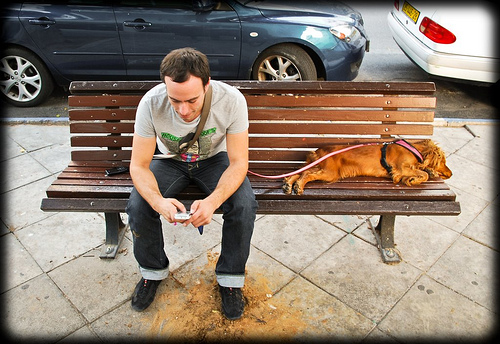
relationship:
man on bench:
[123, 48, 257, 323] [37, 79, 462, 219]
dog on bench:
[275, 137, 457, 197] [37, 79, 462, 219]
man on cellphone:
[123, 48, 257, 323] [171, 210, 193, 221]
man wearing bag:
[123, 48, 257, 323] [139, 81, 215, 160]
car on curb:
[0, 0, 381, 109] [1, 114, 498, 127]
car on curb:
[386, 1, 498, 100] [1, 114, 498, 127]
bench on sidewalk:
[37, 79, 462, 219] [1, 124, 499, 341]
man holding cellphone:
[123, 48, 257, 323] [171, 210, 193, 221]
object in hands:
[174, 213, 192, 224] [153, 196, 214, 227]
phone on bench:
[104, 164, 130, 175] [37, 79, 462, 219]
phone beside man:
[104, 164, 130, 175] [123, 48, 257, 323]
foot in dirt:
[214, 278, 247, 320] [140, 251, 306, 343]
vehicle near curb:
[386, 1, 498, 100] [1, 114, 498, 127]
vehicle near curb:
[0, 0, 381, 109] [1, 114, 498, 127]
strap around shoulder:
[139, 81, 215, 160] [206, 76, 257, 133]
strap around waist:
[139, 81, 215, 160] [148, 149, 245, 164]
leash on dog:
[248, 136, 424, 179] [275, 137, 457, 197]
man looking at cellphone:
[123, 48, 257, 323] [171, 210, 193, 221]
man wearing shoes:
[123, 48, 257, 323] [130, 269, 243, 320]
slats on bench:
[37, 76, 465, 216] [37, 79, 462, 219]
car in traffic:
[0, 0, 381, 109] [2, 0, 498, 118]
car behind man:
[0, 0, 381, 109] [123, 48, 257, 323]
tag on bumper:
[400, 1, 422, 26] [386, 11, 497, 84]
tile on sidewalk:
[1, 123, 499, 344] [1, 124, 499, 341]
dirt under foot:
[140, 251, 306, 343] [214, 278, 247, 320]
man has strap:
[123, 48, 257, 323] [139, 81, 215, 160]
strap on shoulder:
[139, 81, 215, 160] [206, 76, 257, 133]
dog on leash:
[275, 137, 457, 197] [248, 136, 424, 179]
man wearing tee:
[123, 48, 257, 323] [129, 79, 250, 163]